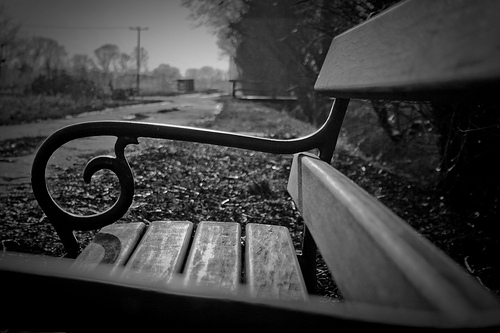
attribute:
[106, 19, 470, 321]
bench — long, wooden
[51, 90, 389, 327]
bench — wooden, long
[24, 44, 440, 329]
bench — wooden, long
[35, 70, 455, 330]
bench — long, wooden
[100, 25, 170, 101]
post — large, wooden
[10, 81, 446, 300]
bench — wooden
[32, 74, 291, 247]
arm — curled, metal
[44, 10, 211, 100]
sky — daytime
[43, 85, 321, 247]
arm — reflecting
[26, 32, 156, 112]
tree — leafless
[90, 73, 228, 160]
street — paved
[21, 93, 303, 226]
arm — metal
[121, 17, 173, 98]
post — tall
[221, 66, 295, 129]
bridge — wooden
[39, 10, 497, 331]
bench — wooden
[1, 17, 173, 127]
trees — tall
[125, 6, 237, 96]
sky — cloudy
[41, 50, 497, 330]
bench — wooden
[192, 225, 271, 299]
plank — wooden